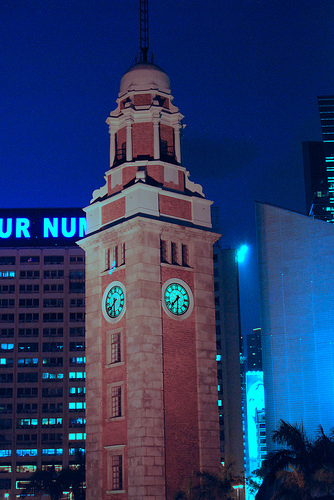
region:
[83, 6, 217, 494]
A tall brick tower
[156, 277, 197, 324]
a round clock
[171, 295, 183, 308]
two hands on the clock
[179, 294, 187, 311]
roman numbers on the clock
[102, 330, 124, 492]
three windows with bars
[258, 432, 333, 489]
a plam tree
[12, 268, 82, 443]
a building with lots of windows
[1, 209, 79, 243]
a neon sign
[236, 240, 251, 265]
lights on top of a building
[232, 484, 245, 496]
street light on a pole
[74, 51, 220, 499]
tall brick tower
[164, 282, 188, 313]
clock on tower is illuminated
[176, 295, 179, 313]
hour hand on clock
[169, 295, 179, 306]
black minute hand on clock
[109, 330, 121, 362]
windows under clock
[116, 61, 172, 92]
small dome on top of tower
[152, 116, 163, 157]
stone columns under dome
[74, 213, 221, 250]
ledge above clock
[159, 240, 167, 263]
small windows under ledge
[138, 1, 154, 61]
lightning rod on top of domw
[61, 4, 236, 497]
tall tower with a clock on it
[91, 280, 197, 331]
clock on either side of the tower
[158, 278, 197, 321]
clock indicating it's 7:30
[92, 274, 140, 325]
clock with roman numerals around it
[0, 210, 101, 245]
sign lit up on top of the building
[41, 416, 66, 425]
three lit windows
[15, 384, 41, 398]
three dark windows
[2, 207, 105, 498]
building with lots of windows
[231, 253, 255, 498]
corner of a building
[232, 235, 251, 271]
light shining in the dark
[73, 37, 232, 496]
a lighted clock tower at night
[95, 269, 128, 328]
illuminated clock face on the left side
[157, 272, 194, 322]
Illuminated clock face on the right side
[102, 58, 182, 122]
dome on the illuminated clock tower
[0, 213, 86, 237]
illuminated letters on the side of the building in the background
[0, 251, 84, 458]
windows of an office building in the background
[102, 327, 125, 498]
three windows under the clock face on the right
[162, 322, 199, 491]
red bricks of the clock tower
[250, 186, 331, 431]
lit building in the background on the right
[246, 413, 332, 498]
palm-like trees in front of the right side of the clock tower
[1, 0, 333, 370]
The sky is blue.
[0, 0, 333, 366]
The sky is clear.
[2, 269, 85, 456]
Lights are on in the building.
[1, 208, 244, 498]
The building is tall.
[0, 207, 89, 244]
Words are on the building.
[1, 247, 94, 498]
The building has windows in it.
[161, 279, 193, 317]
The clock face is white.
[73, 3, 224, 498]
The clock is on a tower.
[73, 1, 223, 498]
The tower is red.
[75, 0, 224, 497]
The tower is made of brick.